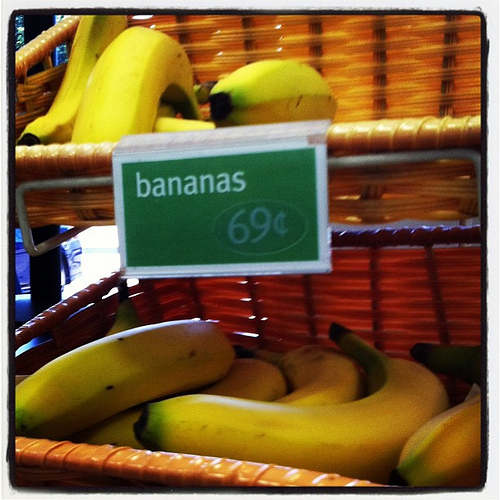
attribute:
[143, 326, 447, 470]
banna — ripe, yellow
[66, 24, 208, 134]
banana — yellow, ripe, long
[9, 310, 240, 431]
banana — ripe, yellow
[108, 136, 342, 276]
sign — green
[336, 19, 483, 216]
basket — brown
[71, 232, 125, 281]
light — showing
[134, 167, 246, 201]
writing — white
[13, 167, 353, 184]
rack — metal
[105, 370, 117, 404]
spot — black